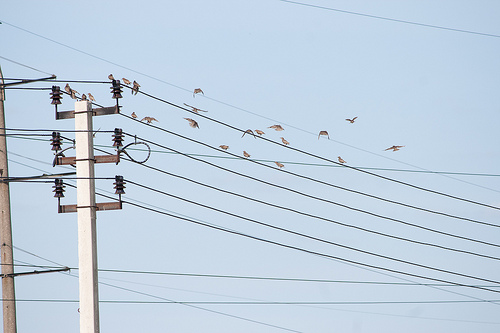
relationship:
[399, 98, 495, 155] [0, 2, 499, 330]
white clouds in sky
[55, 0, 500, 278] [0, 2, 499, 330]
clouds in sky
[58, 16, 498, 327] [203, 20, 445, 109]
clouds in sky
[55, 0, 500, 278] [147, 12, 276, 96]
clouds in sky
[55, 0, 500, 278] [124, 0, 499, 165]
clouds in sky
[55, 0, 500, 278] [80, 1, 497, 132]
clouds in blue sky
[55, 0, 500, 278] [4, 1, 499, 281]
clouds in sky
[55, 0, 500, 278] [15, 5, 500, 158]
clouds in blue sky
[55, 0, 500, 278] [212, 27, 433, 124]
clouds in sky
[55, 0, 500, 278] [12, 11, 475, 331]
clouds in sky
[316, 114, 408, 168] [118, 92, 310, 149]
birds around power line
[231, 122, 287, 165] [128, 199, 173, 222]
birds around power line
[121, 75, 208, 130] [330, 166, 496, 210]
birds around power line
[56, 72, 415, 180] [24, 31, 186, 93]
flock around power line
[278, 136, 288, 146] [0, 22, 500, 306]
bird sitting on cable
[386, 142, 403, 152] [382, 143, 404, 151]
bird with wing spread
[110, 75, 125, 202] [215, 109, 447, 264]
inuslators for power lines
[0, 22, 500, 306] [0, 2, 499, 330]
cable in sky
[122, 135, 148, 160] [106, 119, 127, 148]
looped cable attached to insulator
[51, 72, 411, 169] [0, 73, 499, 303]
birds on wires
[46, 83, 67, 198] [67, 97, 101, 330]
circuits out pylon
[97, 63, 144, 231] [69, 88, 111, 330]
brackets on pole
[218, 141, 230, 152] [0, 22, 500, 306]
bird standing on cable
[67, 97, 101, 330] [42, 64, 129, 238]
pylon with crossbar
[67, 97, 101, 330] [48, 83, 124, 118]
pylon with crossbar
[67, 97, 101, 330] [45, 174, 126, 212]
pylon with crossbar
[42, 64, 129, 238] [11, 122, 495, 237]
crossbar support cable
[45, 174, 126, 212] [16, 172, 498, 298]
crossbar support cable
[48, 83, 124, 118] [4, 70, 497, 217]
crossbar support cable